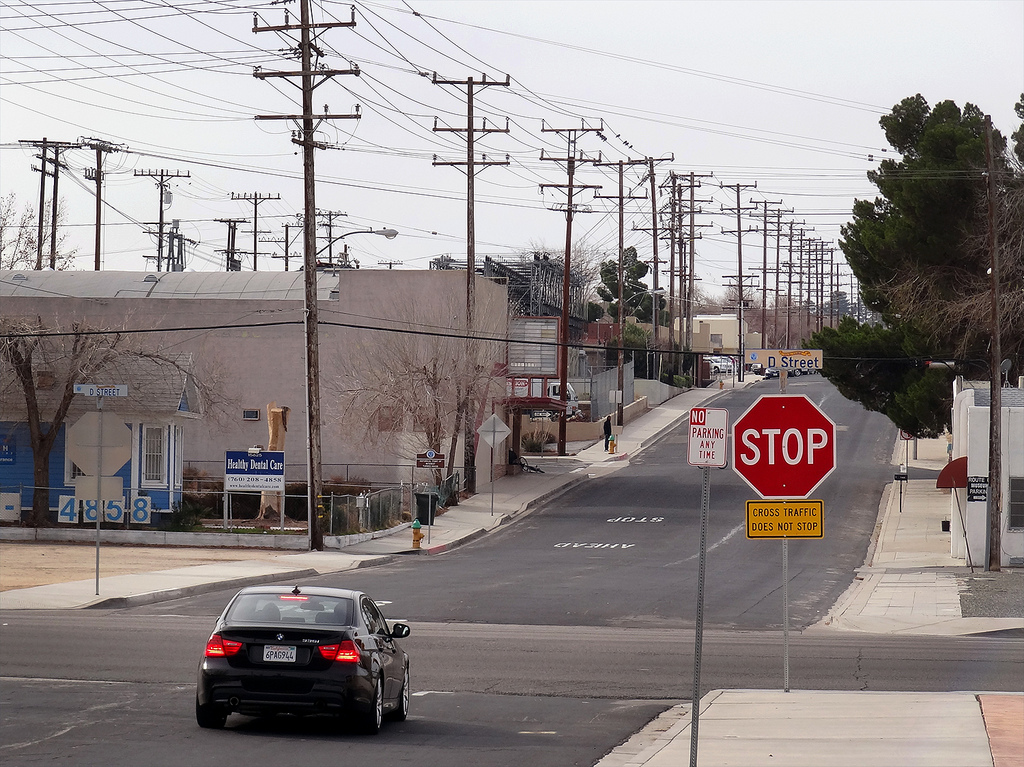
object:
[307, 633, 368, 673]
light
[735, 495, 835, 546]
sign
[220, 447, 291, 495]
sign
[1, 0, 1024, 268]
sky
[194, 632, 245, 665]
lights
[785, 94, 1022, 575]
tree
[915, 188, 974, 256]
leaves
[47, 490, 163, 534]
numbers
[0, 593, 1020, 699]
streets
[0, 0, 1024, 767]
city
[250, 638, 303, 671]
license plate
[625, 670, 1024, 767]
side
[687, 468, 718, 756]
pole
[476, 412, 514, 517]
pole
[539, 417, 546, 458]
pole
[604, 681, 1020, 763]
sidewalk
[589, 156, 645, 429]
pole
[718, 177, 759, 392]
pole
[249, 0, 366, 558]
pole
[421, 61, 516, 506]
pole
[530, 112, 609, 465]
pole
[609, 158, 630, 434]
pole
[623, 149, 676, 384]
pole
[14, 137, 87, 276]
pole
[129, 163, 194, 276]
pole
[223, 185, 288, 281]
pole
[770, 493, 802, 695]
pole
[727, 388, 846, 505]
stop sign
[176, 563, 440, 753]
car